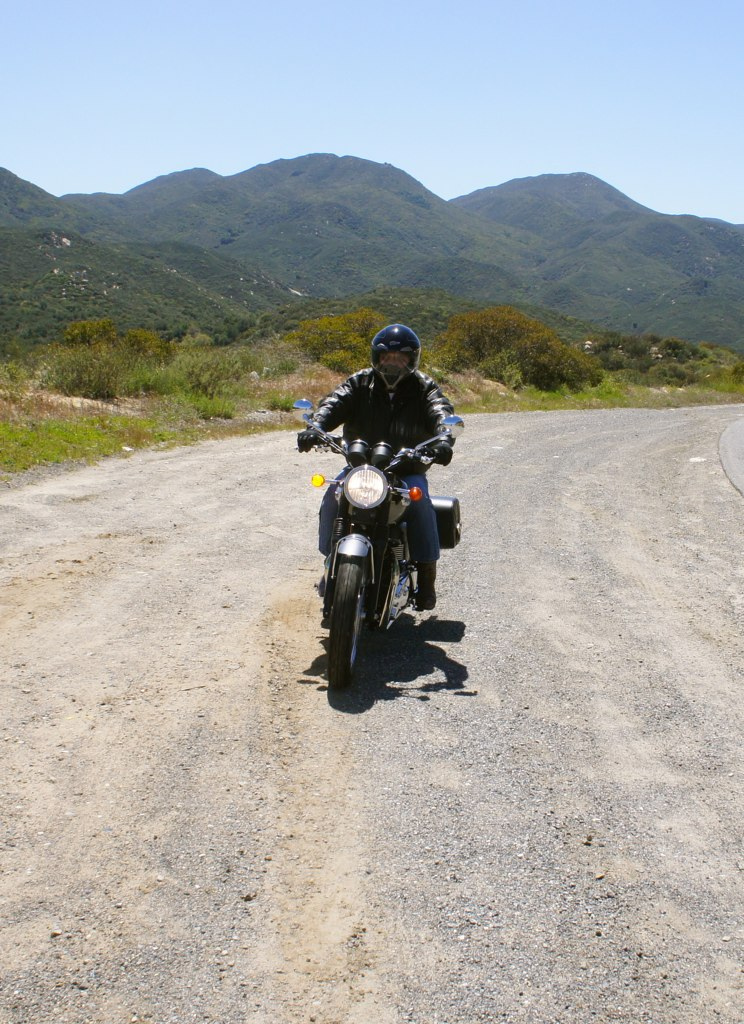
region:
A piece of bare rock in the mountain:
[60, 236, 69, 244]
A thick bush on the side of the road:
[484, 338, 562, 378]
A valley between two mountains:
[307, 283, 359, 295]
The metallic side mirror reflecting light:
[294, 403, 311, 417]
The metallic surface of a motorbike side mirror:
[445, 418, 462, 436]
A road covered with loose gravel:
[391, 761, 556, 917]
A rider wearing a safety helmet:
[378, 329, 410, 350]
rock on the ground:
[241, 892, 263, 903]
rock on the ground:
[330, 937, 390, 974]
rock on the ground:
[581, 826, 612, 844]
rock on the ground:
[60, 964, 80, 992]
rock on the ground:
[277, 726, 295, 747]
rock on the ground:
[654, 959, 671, 984]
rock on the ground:
[578, 829, 603, 860]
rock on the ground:
[516, 732, 544, 756]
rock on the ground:
[282, 744, 304, 771]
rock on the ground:
[444, 967, 484, 995]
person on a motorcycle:
[275, 304, 481, 705]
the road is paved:
[5, 389, 729, 1022]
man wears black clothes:
[282, 312, 471, 615]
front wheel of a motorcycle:
[313, 523, 399, 712]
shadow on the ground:
[386, 606, 488, 714]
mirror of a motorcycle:
[284, 389, 337, 463]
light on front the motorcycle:
[332, 455, 391, 513]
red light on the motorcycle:
[384, 470, 420, 501]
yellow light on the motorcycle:
[299, 455, 334, 494]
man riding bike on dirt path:
[241, 277, 523, 708]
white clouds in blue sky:
[618, 92, 671, 162]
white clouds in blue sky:
[173, 29, 253, 94]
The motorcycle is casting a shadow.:
[285, 393, 469, 707]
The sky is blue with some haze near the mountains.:
[0, 0, 737, 216]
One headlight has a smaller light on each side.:
[306, 460, 419, 501]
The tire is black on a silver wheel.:
[318, 553, 352, 683]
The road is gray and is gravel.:
[0, 399, 734, 1012]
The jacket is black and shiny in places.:
[301, 366, 452, 451]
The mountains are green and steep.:
[0, 150, 739, 306]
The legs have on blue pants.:
[312, 469, 435, 561]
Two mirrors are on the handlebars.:
[291, 397, 465, 461]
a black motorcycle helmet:
[368, 320, 423, 389]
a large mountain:
[438, 172, 651, 244]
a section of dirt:
[257, 590, 321, 740]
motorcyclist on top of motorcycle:
[298, 322, 453, 615]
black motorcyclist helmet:
[367, 322, 421, 386]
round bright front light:
[343, 465, 386, 510]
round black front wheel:
[320, 535, 374, 693]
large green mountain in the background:
[2, 150, 735, 356]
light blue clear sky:
[1, 1, 739, 230]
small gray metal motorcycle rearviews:
[289, 396, 469, 439]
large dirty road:
[1, 401, 740, 1017]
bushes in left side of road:
[1, 296, 687, 466]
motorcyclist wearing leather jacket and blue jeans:
[296, 322, 456, 613]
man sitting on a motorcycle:
[288, 318, 465, 700]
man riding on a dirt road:
[3, 321, 741, 1019]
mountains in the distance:
[1, 150, 739, 398]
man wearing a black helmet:
[298, 323, 463, 470]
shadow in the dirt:
[302, 607, 488, 714]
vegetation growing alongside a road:
[6, 315, 738, 492]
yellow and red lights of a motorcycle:
[306, 471, 426, 505]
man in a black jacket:
[292, 322, 464, 468]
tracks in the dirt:
[489, 420, 741, 665]